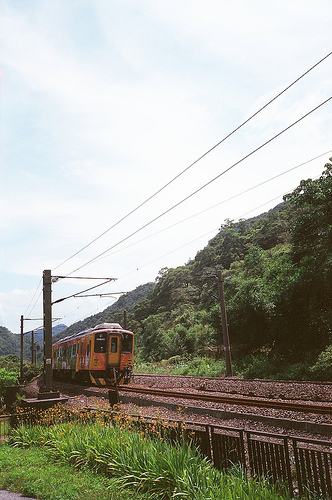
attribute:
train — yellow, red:
[45, 320, 141, 388]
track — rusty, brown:
[29, 362, 331, 444]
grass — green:
[4, 419, 294, 500]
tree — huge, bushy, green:
[278, 161, 331, 356]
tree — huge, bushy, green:
[226, 241, 285, 333]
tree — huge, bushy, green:
[152, 268, 200, 307]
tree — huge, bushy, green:
[187, 321, 216, 357]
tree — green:
[141, 314, 175, 361]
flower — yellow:
[149, 425, 154, 433]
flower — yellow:
[120, 423, 125, 429]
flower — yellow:
[190, 429, 195, 438]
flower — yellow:
[69, 408, 75, 415]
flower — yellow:
[97, 400, 102, 405]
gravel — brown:
[54, 376, 331, 436]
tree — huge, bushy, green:
[148, 317, 182, 355]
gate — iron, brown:
[71, 401, 331, 498]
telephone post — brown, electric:
[39, 267, 56, 386]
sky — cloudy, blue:
[4, 2, 331, 337]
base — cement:
[22, 386, 71, 411]